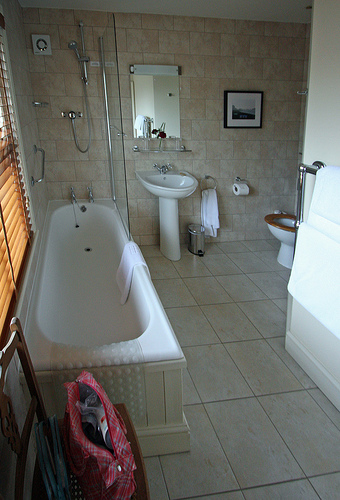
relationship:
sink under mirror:
[135, 165, 201, 263] [127, 60, 184, 152]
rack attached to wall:
[31, 144, 45, 186] [19, 6, 310, 246]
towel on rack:
[201, 188, 222, 236] [290, 159, 324, 225]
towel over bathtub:
[115, 240, 151, 306] [15, 178, 194, 466]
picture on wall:
[222, 85, 265, 126] [211, 127, 276, 165]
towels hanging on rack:
[287, 168, 338, 329] [293, 159, 325, 267]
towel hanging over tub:
[114, 240, 152, 303] [54, 212, 108, 255]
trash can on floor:
[185, 218, 209, 257] [139, 237, 336, 498]